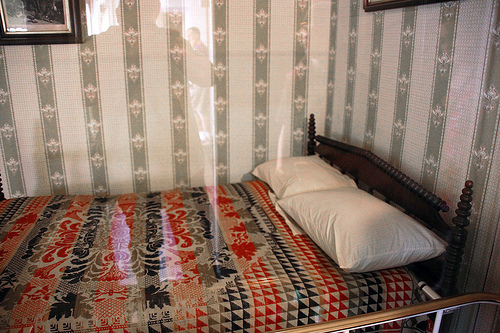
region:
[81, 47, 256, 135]
sheer drape around bed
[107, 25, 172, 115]
black and white pattern on drapes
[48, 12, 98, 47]
black edge of television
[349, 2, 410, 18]
black picture frame on wall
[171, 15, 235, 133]
man standing in the background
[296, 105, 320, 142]
post on the bed frame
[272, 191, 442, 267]
fluffy white pillow on bed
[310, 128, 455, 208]
large wooden bed frame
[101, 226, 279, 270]
red and black sheet on bed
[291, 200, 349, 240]
wrinkles on white pillow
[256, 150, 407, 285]
pillows on the bed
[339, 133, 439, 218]
headboard of the bed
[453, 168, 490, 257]
end of the bed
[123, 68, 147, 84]
design on the wallpaper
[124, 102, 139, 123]
design on the wallpaper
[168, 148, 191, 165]
design on the wallpaper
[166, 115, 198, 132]
design on the wallpaper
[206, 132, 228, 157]
design on the wallpaper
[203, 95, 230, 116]
design on the wallpaper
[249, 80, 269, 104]
design on the wallpaper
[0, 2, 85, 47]
framed picture hanging on wall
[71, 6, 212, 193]
reflection of people on wall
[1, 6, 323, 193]
striped wallpaper on wall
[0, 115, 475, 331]
wood bed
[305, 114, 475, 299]
dark brown wooden headboard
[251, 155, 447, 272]
white pillows resting on bed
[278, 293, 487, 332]
wood and metal bed frame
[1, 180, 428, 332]
red and black quilt on bed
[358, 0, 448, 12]
framed picture hanging on wall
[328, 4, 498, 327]
striped wallpaper on wall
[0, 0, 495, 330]
things in a bedroom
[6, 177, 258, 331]
A colorful designed bedspread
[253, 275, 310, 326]
triangle patterns on bedspread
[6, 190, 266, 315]
Circular pattern on bedspread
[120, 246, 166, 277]
floral pattern on bedspread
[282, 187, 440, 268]
white pillow on bed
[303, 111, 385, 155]
headboard with carved designs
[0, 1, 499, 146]
green and cream wallpaper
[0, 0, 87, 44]
picture frame in the upper right corner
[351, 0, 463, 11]
part of a frame in left upper corner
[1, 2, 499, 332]
The wall is papered.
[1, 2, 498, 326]
The wallpaper is striped.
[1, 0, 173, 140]
The picture is hanging on the wall.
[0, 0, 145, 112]
The picture is framed.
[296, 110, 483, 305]
The headboard is wood.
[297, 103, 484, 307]
The headboard is dark.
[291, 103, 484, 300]
The head board is brown.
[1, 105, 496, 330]
The bed is made.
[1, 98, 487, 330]
The bed is neat.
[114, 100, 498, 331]
Two pillows on the bed.